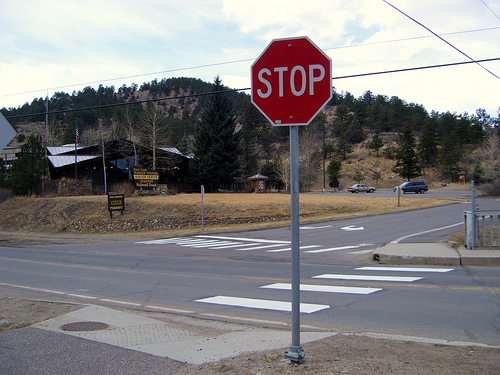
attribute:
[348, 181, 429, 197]
cars — parked, distant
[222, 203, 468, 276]
road — clear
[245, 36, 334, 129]
sign — octagonal, red, white, big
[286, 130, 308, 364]
post — metal, gray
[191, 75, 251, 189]
tree — green, big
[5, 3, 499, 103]
sky — here, blue, cloudy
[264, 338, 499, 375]
ground — sandy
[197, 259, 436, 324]
cross walk — white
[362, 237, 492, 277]
curb — cement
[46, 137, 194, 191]
building — nice, large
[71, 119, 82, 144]
flag — american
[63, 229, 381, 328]
intersection — rural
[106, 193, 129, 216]
sign — small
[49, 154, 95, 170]
roofing — triangular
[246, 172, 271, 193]
kiosk — informational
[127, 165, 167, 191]
sign — black, yellow, large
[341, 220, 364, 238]
arrow — white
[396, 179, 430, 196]
car — black, driving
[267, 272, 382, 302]
line — white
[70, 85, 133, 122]
trees — green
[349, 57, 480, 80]
wire — overhead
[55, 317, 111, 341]
manhole — round